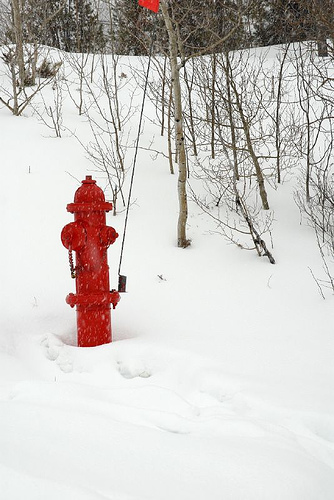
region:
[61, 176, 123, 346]
a tall red fire hydrant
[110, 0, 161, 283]
a tall red flat on pole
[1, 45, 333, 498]
a white snowy field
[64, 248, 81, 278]
a short red chain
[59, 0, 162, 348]
a fire hydrant with flag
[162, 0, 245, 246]
a young bare tree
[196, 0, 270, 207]
a young bare tree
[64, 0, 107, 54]
an evergreen tree in distance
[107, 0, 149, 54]
an evergreen tree in distance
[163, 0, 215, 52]
an evergreen tree in distance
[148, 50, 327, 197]
the trees are bare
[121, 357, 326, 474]
footprints in the snow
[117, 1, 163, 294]
the flag on the hydrant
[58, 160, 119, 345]
the hydrant is red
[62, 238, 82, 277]
the chain on the hydrant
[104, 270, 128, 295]
spring at the base of flag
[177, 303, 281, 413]
the snow on the ground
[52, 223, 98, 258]
the large hydrant cap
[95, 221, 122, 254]
the small hydrant cap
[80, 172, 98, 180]
the lug on top of the hydrant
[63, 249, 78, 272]
a chain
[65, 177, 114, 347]
red fire hydrant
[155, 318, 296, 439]
the snow is white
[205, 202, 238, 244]
tree branches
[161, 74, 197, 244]
a tree trunk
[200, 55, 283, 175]
tree branches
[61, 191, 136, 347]
the fire hydrant is red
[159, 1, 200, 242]
a tall tree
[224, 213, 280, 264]
the tree branch is in the snow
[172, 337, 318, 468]
the white snow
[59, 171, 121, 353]
Extra High Red Fire Hydrant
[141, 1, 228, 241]
White Bare Birch Tree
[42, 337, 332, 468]
Deep Footprints In The Snow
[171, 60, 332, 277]
Small Bare Stick Trees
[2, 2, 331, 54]
Large Kept Pine Trees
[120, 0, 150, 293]
Red Flag Marker On Hydrant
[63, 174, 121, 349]
Falling Snow Flakes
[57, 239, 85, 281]
Rusty Chain Hanging From Hydrant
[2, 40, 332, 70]
Large Snowbank ledges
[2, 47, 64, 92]
Small Snow Covered Shrubs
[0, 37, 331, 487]
snow covered ground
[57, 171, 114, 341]
red fire hydrant in the snow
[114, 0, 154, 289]
red flag on a wire pole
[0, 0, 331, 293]
bare trees in the snow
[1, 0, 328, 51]
green pine trees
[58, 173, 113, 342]
chain hanging on fire hydrant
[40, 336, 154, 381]
tracks in the snow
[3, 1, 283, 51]
gray sky seen through the trees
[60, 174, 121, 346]
red bolt on top of a fire hydrant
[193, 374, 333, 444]
foot prints in the snow